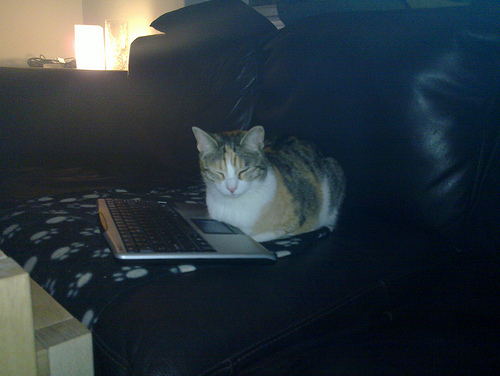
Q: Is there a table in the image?
A: Yes, there is a table.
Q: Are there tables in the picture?
A: Yes, there is a table.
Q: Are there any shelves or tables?
A: Yes, there is a table.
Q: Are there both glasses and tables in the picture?
A: No, there is a table but no glasses.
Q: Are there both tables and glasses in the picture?
A: No, there is a table but no glasses.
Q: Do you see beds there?
A: No, there are no beds.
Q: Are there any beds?
A: No, there are no beds.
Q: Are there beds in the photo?
A: No, there are no beds.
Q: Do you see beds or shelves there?
A: No, there are no beds or shelves.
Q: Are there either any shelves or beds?
A: No, there are no beds or shelves.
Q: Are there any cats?
A: Yes, there is a cat.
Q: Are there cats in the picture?
A: Yes, there is a cat.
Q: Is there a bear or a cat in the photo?
A: Yes, there is a cat.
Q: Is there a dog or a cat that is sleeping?
A: Yes, the cat is sleeping.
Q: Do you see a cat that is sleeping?
A: Yes, there is a cat that is sleeping.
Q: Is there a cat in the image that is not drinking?
A: Yes, there is a cat that is sleeping.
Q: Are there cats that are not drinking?
A: Yes, there is a cat that is sleeping.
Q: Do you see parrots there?
A: No, there are no parrots.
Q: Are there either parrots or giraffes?
A: No, there are no parrots or giraffes.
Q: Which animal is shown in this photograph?
A: The animal is a cat.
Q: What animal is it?
A: The animal is a cat.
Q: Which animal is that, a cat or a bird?
A: That is a cat.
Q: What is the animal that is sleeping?
A: The animal is a cat.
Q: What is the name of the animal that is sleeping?
A: The animal is a cat.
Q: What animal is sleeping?
A: The animal is a cat.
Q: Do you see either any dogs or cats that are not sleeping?
A: No, there is a cat but it is sleeping.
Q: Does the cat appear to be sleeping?
A: Yes, the cat is sleeping.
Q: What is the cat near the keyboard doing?
A: The cat is sleeping.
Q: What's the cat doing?
A: The cat is sleeping.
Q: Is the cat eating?
A: No, the cat is sleeping.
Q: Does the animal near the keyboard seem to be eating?
A: No, the cat is sleeping.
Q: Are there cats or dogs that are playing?
A: No, there is a cat but it is sleeping.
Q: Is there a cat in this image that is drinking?
A: No, there is a cat but it is sleeping.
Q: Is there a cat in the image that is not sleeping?
A: No, there is a cat but it is sleeping.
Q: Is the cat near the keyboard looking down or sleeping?
A: The cat is sleeping.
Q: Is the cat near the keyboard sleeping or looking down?
A: The cat is sleeping.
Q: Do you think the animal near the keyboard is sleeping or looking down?
A: The cat is sleeping.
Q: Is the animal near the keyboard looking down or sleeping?
A: The cat is sleeping.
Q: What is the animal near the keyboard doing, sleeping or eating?
A: The cat is sleeping.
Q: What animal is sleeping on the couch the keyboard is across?
A: The animal is a cat.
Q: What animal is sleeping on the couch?
A: The animal is a cat.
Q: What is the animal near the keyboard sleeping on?
A: The cat is sleeping on the couch.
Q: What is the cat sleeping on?
A: The cat is sleeping on the couch.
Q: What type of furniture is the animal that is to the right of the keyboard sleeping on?
A: The cat is sleeping on the couch.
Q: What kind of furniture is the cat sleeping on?
A: The cat is sleeping on the couch.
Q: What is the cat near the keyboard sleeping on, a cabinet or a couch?
A: The cat is sleeping on a couch.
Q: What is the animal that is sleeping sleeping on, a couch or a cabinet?
A: The cat is sleeping on a couch.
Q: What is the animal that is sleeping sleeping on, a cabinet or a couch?
A: The cat is sleeping on a couch.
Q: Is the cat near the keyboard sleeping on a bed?
A: No, the cat is sleeping on the couch.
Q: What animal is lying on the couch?
A: The animal is a cat.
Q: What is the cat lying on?
A: The cat is lying on the couch.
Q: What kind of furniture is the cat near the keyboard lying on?
A: The cat is lying on the couch.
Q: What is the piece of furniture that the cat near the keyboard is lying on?
A: The piece of furniture is a couch.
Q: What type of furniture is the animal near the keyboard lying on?
A: The cat is lying on the couch.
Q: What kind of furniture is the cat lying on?
A: The cat is lying on the couch.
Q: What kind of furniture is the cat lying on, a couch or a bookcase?
A: The cat is lying on a couch.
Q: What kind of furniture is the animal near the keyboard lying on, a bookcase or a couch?
A: The cat is lying on a couch.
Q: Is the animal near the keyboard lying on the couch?
A: Yes, the cat is lying on the couch.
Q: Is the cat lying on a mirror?
A: No, the cat is lying on the couch.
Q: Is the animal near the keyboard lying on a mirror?
A: No, the cat is lying on the couch.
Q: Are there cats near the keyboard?
A: Yes, there is a cat near the keyboard.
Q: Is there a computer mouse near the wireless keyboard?
A: No, there is a cat near the keyboard.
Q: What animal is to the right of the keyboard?
A: The animal is a cat.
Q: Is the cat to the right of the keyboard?
A: Yes, the cat is to the right of the keyboard.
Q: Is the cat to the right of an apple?
A: No, the cat is to the right of the keyboard.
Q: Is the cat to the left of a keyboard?
A: No, the cat is to the right of a keyboard.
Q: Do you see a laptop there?
A: Yes, there is a laptop.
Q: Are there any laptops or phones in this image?
A: Yes, there is a laptop.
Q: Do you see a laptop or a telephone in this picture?
A: Yes, there is a laptop.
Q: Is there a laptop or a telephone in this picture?
A: Yes, there is a laptop.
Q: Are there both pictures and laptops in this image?
A: No, there is a laptop but no pictures.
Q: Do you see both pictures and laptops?
A: No, there is a laptop but no pictures.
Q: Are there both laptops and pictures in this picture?
A: No, there is a laptop but no pictures.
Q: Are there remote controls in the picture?
A: No, there are no remote controls.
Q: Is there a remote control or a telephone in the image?
A: No, there are no remote controls or phones.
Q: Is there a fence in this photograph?
A: No, there are no fences.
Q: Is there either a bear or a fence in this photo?
A: No, there are no fences or bears.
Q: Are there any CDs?
A: No, there are no cds.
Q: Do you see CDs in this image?
A: No, there are no cds.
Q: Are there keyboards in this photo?
A: Yes, there is a keyboard.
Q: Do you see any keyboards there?
A: Yes, there is a keyboard.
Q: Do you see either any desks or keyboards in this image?
A: Yes, there is a keyboard.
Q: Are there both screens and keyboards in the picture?
A: No, there is a keyboard but no screens.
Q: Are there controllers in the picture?
A: No, there are no controllers.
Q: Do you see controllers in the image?
A: No, there are no controllers.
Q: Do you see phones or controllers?
A: No, there are no controllers or phones.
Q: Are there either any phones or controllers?
A: No, there are no controllers or phones.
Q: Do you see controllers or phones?
A: No, there are no controllers or phones.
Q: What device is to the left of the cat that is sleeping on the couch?
A: The device is a keyboard.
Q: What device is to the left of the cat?
A: The device is a keyboard.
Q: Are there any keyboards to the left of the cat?
A: Yes, there is a keyboard to the left of the cat.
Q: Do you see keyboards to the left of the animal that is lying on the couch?
A: Yes, there is a keyboard to the left of the cat.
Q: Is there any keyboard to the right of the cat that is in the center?
A: No, the keyboard is to the left of the cat.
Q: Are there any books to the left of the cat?
A: No, there is a keyboard to the left of the cat.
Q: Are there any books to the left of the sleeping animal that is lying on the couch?
A: No, there is a keyboard to the left of the cat.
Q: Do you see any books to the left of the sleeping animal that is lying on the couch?
A: No, there is a keyboard to the left of the cat.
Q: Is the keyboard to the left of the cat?
A: Yes, the keyboard is to the left of the cat.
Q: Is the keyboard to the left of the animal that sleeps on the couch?
A: Yes, the keyboard is to the left of the cat.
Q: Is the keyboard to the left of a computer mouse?
A: No, the keyboard is to the left of the cat.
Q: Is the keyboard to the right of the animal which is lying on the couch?
A: No, the keyboard is to the left of the cat.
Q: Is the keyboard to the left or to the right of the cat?
A: The keyboard is to the left of the cat.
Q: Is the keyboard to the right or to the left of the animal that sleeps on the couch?
A: The keyboard is to the left of the cat.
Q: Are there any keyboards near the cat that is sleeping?
A: Yes, there is a keyboard near the cat.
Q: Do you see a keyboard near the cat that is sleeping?
A: Yes, there is a keyboard near the cat.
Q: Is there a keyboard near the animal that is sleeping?
A: Yes, there is a keyboard near the cat.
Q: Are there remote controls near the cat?
A: No, there is a keyboard near the cat.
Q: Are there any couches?
A: Yes, there is a couch.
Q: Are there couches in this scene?
A: Yes, there is a couch.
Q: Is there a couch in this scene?
A: Yes, there is a couch.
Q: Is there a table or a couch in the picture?
A: Yes, there is a couch.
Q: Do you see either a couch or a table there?
A: Yes, there is a couch.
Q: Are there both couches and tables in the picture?
A: Yes, there are both a couch and a table.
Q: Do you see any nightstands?
A: No, there are no nightstands.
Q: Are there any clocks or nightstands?
A: No, there are no nightstands or clocks.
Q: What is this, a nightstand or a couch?
A: This is a couch.